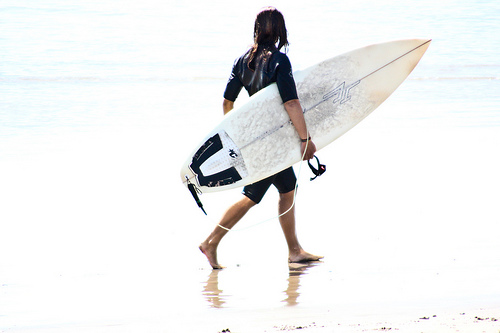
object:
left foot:
[288, 250, 325, 263]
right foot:
[198, 244, 228, 270]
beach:
[0, 142, 497, 333]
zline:
[187, 132, 243, 189]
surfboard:
[177, 37, 432, 194]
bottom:
[187, 129, 249, 190]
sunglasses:
[307, 154, 327, 181]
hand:
[300, 139, 316, 162]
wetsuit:
[222, 47, 300, 204]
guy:
[198, 5, 327, 270]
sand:
[234, 306, 500, 332]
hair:
[245, 6, 290, 71]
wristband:
[300, 136, 311, 142]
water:
[1, 1, 499, 128]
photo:
[1, 1, 499, 332]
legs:
[205, 165, 274, 245]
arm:
[274, 54, 312, 142]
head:
[251, 7, 288, 44]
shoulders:
[231, 46, 292, 76]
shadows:
[199, 263, 304, 310]